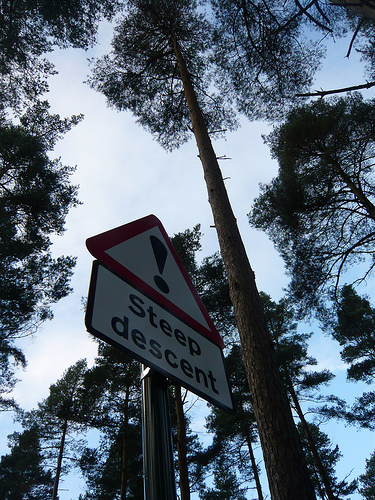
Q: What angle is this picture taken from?
A: From below.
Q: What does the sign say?
A: Steep descent.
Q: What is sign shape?
A: Rectangle.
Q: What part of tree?
A: Trunk.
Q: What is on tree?
A: Leaves.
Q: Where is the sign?
A: Ground.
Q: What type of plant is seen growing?
A: Trees.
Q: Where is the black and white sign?
A: On the metal pole.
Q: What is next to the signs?
A: Tall evergreen tree.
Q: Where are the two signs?
A: On a metal post.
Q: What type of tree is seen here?
A: Tall evergreen trees.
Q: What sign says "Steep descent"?
A: Black and white one.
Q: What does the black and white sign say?
A: Steep descent.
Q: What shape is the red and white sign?
A: Triangle.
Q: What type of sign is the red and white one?
A: Warning sign.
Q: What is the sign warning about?
A: The steep descent.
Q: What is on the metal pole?
A: Two signs.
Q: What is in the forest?
A: Several very tall pine trees.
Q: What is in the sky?
A: Trees.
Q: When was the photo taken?
A: Day time.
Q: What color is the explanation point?
A: Black.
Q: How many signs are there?
A: Two.